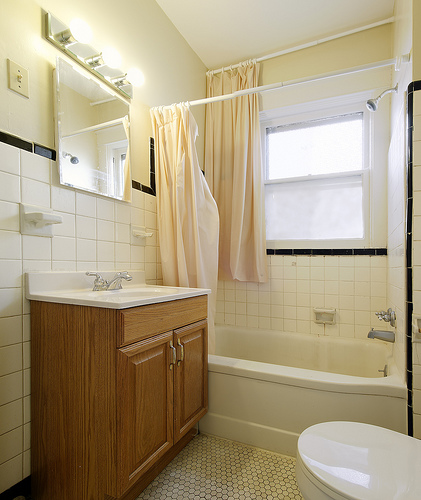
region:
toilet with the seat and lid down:
[293, 419, 420, 498]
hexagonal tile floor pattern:
[135, 430, 304, 499]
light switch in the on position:
[6, 56, 28, 98]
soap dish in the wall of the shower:
[312, 306, 337, 324]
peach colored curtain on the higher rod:
[200, 55, 263, 280]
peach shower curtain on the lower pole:
[147, 97, 216, 351]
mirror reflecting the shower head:
[53, 52, 131, 204]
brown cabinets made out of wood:
[27, 292, 208, 498]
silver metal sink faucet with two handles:
[83, 270, 131, 291]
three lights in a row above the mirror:
[44, 11, 145, 100]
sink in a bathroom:
[20, 259, 214, 314]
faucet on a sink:
[83, 266, 135, 296]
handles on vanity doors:
[164, 334, 189, 373]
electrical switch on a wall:
[4, 54, 32, 103]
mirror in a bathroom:
[48, 52, 137, 207]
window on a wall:
[252, 84, 384, 256]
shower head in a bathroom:
[363, 77, 403, 116]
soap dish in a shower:
[308, 303, 342, 328]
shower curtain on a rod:
[145, 97, 223, 362]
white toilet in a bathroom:
[284, 414, 416, 498]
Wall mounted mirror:
[53, 54, 133, 203]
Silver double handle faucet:
[83, 269, 134, 291]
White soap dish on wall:
[15, 199, 61, 239]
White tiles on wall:
[58, 202, 131, 265]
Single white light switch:
[6, 57, 29, 99]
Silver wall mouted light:
[47, 11, 132, 102]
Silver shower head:
[364, 82, 398, 112]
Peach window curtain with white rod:
[206, 50, 269, 281]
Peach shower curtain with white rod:
[150, 91, 220, 289]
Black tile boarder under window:
[264, 245, 387, 258]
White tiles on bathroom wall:
[217, 255, 386, 339]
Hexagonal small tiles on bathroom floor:
[137, 432, 301, 498]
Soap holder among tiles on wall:
[19, 203, 61, 236]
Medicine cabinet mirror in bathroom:
[56, 56, 130, 202]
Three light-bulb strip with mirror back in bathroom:
[45, 11, 144, 95]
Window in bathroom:
[261, 113, 364, 239]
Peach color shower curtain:
[148, 101, 219, 353]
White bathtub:
[200, 322, 406, 456]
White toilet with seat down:
[295, 420, 418, 499]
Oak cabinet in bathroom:
[32, 293, 205, 498]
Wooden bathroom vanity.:
[19, 268, 212, 498]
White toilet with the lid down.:
[296, 417, 419, 498]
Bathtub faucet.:
[366, 324, 397, 343]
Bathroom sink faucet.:
[85, 267, 137, 292]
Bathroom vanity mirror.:
[57, 69, 138, 201]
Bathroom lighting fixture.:
[43, 16, 145, 98]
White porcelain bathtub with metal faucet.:
[228, 323, 406, 442]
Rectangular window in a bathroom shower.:
[257, 111, 375, 245]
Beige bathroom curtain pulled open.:
[202, 59, 269, 280]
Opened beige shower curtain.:
[149, 101, 217, 292]